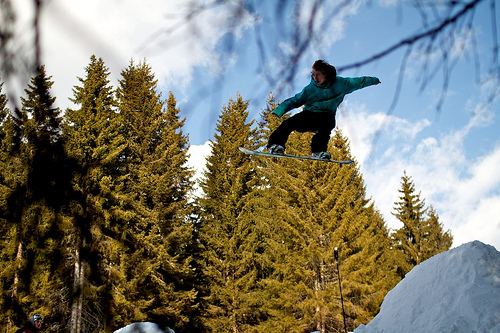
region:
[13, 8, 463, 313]
a skateboarder flying high into the air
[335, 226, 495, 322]
a pile of snow in the area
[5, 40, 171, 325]
pine trees in the scene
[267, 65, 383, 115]
the snowboarder is moving through the air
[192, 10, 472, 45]
tree branches above this person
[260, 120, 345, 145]
black pants on the snowboarder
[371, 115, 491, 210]
clouds in the sky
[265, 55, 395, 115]
the snowboarder's arms are extended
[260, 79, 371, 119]
he has on a green ski coat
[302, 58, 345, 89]
this person is not wearing a hat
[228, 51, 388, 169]
a person with the snowboard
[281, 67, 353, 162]
a person wearing snowsuit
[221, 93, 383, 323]
pine trees near the snow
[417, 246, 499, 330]
mountain full of snow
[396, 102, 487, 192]
blue sky with clouds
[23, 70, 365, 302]
lots of pine trees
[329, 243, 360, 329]
lamp with metal post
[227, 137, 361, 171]
sky color snowboard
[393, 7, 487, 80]
branches of the tree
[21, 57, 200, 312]
snow and pine trees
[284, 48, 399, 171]
this is a woman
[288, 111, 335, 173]
this is a snowboarder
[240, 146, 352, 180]
this is a snowboard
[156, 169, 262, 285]
this is a pine tree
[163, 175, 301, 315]
the tree is mud green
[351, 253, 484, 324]
this is snow mountain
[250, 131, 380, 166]
these are some shoes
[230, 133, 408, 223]
the shoes are white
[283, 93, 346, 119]
the jacket is teal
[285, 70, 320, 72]
this is a head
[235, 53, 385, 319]
snowboarder high over ground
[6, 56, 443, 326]
yellowish-green trees in a row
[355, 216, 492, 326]
mound of smooth white snow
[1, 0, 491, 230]
blue sky with white clouds above snowboarder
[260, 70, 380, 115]
arms extended and slanted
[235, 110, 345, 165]
knees bent over board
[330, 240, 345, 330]
black pole with black device and white panel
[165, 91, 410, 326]
branches pointing upward on trees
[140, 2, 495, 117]
leafless branches hanging down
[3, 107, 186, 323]
dark lines of shadow radiating across tree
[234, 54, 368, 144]
MAN SNOW BOARDING IN MID AIR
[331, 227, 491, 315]
SNOW HILL ON RIGHT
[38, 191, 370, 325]
THICK FOREST IN BACKGROUND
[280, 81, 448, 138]
TEAL JACKET ON MAN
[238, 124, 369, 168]
SNOWBOARD UNDER MAN'S FEET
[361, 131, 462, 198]
WHITE CLOUDS IN SKY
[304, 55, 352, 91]
GOGGLES ON MAN'S HEAD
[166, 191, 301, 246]
GREEN LEAVES OF TREES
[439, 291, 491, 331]
THICK WHTIE SNOW ON GROUND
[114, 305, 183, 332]
SNOW HILL ON LEFT